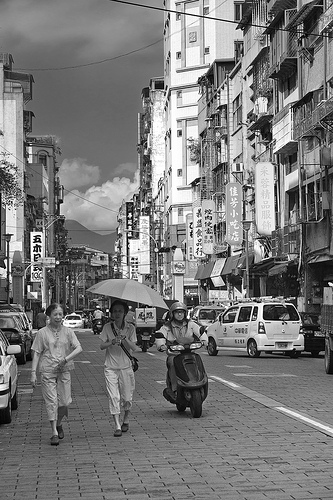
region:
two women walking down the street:
[30, 278, 162, 461]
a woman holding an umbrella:
[80, 273, 170, 437]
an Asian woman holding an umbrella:
[81, 268, 176, 439]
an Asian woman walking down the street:
[22, 291, 91, 455]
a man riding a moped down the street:
[154, 294, 222, 423]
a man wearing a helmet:
[161, 301, 197, 327]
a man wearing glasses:
[164, 299, 197, 328]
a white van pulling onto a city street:
[199, 299, 308, 370]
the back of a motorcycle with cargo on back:
[133, 303, 156, 356]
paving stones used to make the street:
[16, 439, 328, 496]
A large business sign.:
[29, 230, 44, 282]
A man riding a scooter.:
[154, 301, 209, 418]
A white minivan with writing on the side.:
[202, 297, 305, 355]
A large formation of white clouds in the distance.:
[57, 157, 139, 235]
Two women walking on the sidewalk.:
[28, 277, 169, 445]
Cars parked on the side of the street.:
[0, 302, 32, 424]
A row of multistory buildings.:
[113, 0, 331, 301]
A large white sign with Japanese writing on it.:
[255, 160, 273, 235]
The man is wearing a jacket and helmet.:
[156, 302, 208, 396]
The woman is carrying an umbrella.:
[84, 278, 170, 436]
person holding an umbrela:
[88, 271, 172, 433]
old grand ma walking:
[23, 291, 83, 444]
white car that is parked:
[0, 321, 25, 423]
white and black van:
[196, 286, 305, 358]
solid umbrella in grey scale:
[86, 266, 171, 320]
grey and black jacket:
[155, 312, 205, 360]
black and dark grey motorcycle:
[160, 342, 207, 412]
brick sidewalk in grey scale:
[25, 417, 320, 498]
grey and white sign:
[190, 257, 234, 282]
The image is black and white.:
[0, 0, 332, 499]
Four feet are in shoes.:
[51, 422, 129, 446]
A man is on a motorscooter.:
[155, 303, 208, 415]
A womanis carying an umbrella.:
[83, 277, 168, 435]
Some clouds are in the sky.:
[1, 0, 164, 252]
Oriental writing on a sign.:
[29, 230, 41, 280]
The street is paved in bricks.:
[0, 324, 332, 495]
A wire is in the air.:
[0, 141, 130, 217]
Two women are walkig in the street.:
[25, 301, 138, 445]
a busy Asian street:
[20, 208, 298, 445]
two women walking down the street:
[26, 268, 165, 451]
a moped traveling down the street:
[151, 296, 224, 415]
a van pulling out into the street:
[200, 294, 310, 361]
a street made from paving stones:
[27, 433, 326, 491]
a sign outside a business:
[27, 228, 47, 290]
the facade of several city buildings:
[124, 25, 321, 267]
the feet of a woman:
[42, 423, 71, 446]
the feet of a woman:
[101, 419, 136, 442]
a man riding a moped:
[145, 296, 211, 356]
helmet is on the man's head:
[168, 300, 189, 322]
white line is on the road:
[275, 402, 332, 434]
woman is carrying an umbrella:
[84, 276, 170, 437]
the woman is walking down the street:
[29, 301, 83, 447]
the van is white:
[203, 297, 304, 357]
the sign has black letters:
[26, 229, 44, 282]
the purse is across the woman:
[109, 321, 139, 371]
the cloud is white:
[59, 171, 144, 236]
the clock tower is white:
[171, 246, 186, 305]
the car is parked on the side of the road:
[0, 327, 23, 427]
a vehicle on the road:
[200, 302, 206, 323]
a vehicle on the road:
[313, 286, 332, 348]